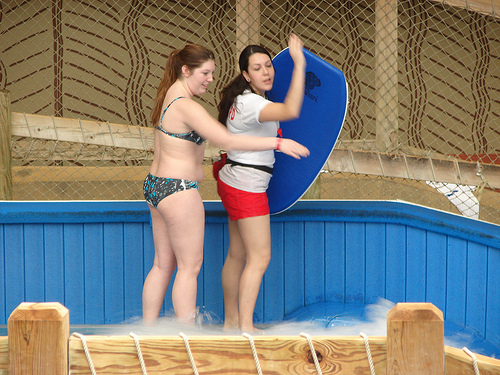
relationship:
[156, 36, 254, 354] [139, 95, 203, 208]
woman wearing bathing suit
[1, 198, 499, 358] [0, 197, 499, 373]
sides of wading pool